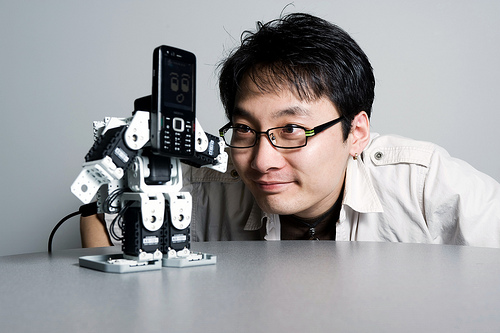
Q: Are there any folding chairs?
A: No, there are no folding chairs.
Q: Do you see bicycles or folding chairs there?
A: No, there are no folding chairs or bicycles.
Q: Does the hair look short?
A: Yes, the hair is short.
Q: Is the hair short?
A: Yes, the hair is short.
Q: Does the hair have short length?
A: Yes, the hair is short.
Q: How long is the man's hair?
A: The hair is short.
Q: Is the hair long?
A: No, the hair is short.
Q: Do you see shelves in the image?
A: No, there are no shelves.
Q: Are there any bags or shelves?
A: No, there are no shelves or bags.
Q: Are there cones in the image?
A: No, there are no cones.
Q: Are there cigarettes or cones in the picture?
A: No, there are no cones or cigarettes.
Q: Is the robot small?
A: Yes, the robot is small.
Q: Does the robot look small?
A: Yes, the robot is small.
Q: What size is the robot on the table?
A: The robot is small.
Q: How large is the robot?
A: The robot is small.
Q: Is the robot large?
A: No, the robot is small.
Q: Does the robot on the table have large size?
A: No, the robot is small.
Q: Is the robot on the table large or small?
A: The robot is small.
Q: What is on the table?
A: The robot is on the table.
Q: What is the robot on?
A: The robot is on the table.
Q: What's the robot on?
A: The robot is on the table.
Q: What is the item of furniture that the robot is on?
A: The piece of furniture is a table.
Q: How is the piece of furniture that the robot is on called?
A: The piece of furniture is a table.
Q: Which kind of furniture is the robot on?
A: The robot is on the table.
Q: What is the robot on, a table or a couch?
A: The robot is on a table.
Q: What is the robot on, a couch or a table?
A: The robot is on a table.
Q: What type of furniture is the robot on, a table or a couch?
A: The robot is on a table.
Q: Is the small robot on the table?
A: Yes, the robot is on the table.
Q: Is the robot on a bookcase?
A: No, the robot is on the table.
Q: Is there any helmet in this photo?
A: No, there are no helmets.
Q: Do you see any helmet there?
A: No, there are no helmets.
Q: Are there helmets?
A: No, there are no helmets.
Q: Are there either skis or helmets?
A: No, there are no helmets or skis.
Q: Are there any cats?
A: No, there are no cats.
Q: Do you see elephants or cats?
A: No, there are no cats or elephants.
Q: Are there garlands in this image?
A: No, there are no garlands.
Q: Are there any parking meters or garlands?
A: No, there are no garlands or parking meters.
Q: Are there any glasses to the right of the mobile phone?
A: Yes, there are glasses to the right of the mobile phone.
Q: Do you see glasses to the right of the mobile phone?
A: Yes, there are glasses to the right of the mobile phone.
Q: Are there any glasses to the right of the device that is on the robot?
A: Yes, there are glasses to the right of the mobile phone.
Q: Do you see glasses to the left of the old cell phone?
A: No, the glasses are to the right of the mobile phone.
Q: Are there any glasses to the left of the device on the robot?
A: No, the glasses are to the right of the mobile phone.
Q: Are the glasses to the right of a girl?
A: No, the glasses are to the right of the mobile phone.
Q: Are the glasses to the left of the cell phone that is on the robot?
A: No, the glasses are to the right of the cell phone.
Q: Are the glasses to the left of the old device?
A: No, the glasses are to the right of the cell phone.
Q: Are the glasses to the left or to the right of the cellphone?
A: The glasses are to the right of the cellphone.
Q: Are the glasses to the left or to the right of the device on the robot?
A: The glasses are to the right of the cellphone.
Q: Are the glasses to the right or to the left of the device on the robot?
A: The glasses are to the right of the cellphone.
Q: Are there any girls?
A: No, there are no girls.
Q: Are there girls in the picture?
A: No, there are no girls.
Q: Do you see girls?
A: No, there are no girls.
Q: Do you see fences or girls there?
A: No, there are no girls or fences.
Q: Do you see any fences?
A: No, there are no fences.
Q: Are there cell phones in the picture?
A: Yes, there is a cell phone.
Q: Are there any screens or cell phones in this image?
A: Yes, there is a cell phone.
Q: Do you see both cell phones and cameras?
A: No, there is a cell phone but no cameras.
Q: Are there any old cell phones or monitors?
A: Yes, there is an old cell phone.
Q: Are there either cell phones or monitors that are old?
A: Yes, the cell phone is old.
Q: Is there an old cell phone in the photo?
A: Yes, there is an old cell phone.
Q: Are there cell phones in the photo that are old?
A: Yes, there is a cell phone that is old.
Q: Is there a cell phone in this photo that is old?
A: Yes, there is a cell phone that is old.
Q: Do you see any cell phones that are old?
A: Yes, there is a cell phone that is old.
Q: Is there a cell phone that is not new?
A: Yes, there is a old cell phone.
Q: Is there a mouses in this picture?
A: No, there are no computer mousess.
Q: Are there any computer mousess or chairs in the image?
A: No, there are no computer mousess or chairs.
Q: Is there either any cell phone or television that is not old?
A: No, there is a cell phone but it is old.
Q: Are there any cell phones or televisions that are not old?
A: No, there is a cell phone but it is old.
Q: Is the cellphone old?
A: Yes, the cellphone is old.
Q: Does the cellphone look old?
A: Yes, the cellphone is old.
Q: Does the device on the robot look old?
A: Yes, the cellphone is old.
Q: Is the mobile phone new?
A: No, the mobile phone is old.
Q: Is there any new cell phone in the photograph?
A: No, there is a cell phone but it is old.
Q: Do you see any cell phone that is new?
A: No, there is a cell phone but it is old.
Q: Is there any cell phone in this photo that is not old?
A: No, there is a cell phone but it is old.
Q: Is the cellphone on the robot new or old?
A: The cellphone is old.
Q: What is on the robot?
A: The cellphone is on the robot.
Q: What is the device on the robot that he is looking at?
A: The device is a cell phone.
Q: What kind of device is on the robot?
A: The device is a cell phone.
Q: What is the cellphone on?
A: The cellphone is on the robot.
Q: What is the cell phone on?
A: The cellphone is on the robot.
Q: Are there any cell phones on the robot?
A: Yes, there is a cell phone on the robot.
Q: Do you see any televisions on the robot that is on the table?
A: No, there is a cell phone on the robot.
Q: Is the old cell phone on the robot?
A: Yes, the cellphone is on the robot.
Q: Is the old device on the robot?
A: Yes, the cellphone is on the robot.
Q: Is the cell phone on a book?
A: No, the cell phone is on the robot.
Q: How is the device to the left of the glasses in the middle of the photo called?
A: The device is a cell phone.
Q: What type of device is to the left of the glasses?
A: The device is a cell phone.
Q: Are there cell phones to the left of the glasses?
A: Yes, there is a cell phone to the left of the glasses.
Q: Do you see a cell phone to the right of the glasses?
A: No, the cell phone is to the left of the glasses.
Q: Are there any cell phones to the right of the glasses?
A: No, the cell phone is to the left of the glasses.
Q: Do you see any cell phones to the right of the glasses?
A: No, the cell phone is to the left of the glasses.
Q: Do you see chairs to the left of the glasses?
A: No, there is a cell phone to the left of the glasses.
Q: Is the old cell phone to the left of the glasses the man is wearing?
A: Yes, the cell phone is to the left of the glasses.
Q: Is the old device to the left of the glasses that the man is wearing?
A: Yes, the cell phone is to the left of the glasses.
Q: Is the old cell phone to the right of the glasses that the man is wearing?
A: No, the cell phone is to the left of the glasses.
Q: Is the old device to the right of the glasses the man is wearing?
A: No, the cell phone is to the left of the glasses.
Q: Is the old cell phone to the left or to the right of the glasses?
A: The cell phone is to the left of the glasses.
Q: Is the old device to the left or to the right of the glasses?
A: The cell phone is to the left of the glasses.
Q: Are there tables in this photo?
A: Yes, there is a table.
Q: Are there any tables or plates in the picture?
A: Yes, there is a table.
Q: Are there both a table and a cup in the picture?
A: No, there is a table but no cups.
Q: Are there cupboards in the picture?
A: No, there are no cupboards.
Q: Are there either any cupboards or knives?
A: No, there are no cupboards or knives.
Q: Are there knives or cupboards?
A: No, there are no cupboards or knives.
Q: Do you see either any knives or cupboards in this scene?
A: No, there are no cupboards or knives.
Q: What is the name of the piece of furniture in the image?
A: The piece of furniture is a table.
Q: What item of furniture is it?
A: The piece of furniture is a table.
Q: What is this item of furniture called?
A: This is a table.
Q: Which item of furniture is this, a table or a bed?
A: This is a table.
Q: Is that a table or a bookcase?
A: That is a table.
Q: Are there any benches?
A: No, there are no benches.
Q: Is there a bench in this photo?
A: No, there are no benches.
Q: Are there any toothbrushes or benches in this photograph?
A: No, there are no benches or toothbrushes.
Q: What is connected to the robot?
A: The wires are connected to the robot.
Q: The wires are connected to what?
A: The wires are connected to the robot.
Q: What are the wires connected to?
A: The wires are connected to the robot.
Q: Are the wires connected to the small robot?
A: Yes, the wires are connected to the robot.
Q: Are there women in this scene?
A: No, there are no women.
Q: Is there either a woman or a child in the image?
A: No, there are no women or children.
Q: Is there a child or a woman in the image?
A: No, there are no women or children.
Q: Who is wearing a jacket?
A: The man is wearing a jacket.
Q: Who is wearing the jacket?
A: The man is wearing a jacket.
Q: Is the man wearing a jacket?
A: Yes, the man is wearing a jacket.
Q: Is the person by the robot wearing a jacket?
A: Yes, the man is wearing a jacket.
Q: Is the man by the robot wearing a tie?
A: No, the man is wearing a jacket.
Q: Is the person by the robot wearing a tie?
A: No, the man is wearing a jacket.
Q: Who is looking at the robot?
A: The man is looking at the robot.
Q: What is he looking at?
A: The man is looking at the robot.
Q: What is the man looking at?
A: The man is looking at the robot.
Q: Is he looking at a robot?
A: Yes, the man is looking at a robot.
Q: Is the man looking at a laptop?
A: No, the man is looking at a robot.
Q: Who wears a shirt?
A: The man wears a shirt.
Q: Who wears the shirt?
A: The man wears a shirt.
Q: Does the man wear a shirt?
A: Yes, the man wears a shirt.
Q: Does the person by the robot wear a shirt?
A: Yes, the man wears a shirt.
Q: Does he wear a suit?
A: No, the man wears a shirt.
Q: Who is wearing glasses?
A: The man is wearing glasses.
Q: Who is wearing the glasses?
A: The man is wearing glasses.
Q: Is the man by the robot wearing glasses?
A: Yes, the man is wearing glasses.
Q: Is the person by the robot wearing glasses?
A: Yes, the man is wearing glasses.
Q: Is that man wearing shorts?
A: No, the man is wearing glasses.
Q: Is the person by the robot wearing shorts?
A: No, the man is wearing glasses.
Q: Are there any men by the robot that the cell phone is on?
A: Yes, there is a man by the robot.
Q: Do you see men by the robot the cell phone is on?
A: Yes, there is a man by the robot.